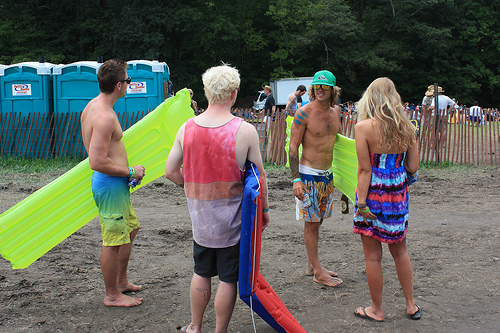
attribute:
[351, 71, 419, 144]
hair — long, blonde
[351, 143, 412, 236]
dress — multi-colored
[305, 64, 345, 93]
hat — green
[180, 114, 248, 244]
tank top — pink, grey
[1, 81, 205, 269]
float — yellow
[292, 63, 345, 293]
man — green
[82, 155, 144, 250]
shorts — multicolored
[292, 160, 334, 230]
shorts — multicolored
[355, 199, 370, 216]
bracelet — green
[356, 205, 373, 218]
wrist — girl's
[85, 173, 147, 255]
shorts — blue, yellow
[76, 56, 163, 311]
guy — brown haired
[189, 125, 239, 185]
section — red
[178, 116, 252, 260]
top — tank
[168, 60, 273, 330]
guy — blond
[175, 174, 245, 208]
section — brown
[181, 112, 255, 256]
top — tank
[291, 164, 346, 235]
shorts — multicolored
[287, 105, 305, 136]
stripes — three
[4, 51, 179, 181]
potties — three, porta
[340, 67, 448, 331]
girl — blonde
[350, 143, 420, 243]
dress — summer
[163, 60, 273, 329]
man — blond, barefoot, young, blonde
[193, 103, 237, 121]
neck — sunburned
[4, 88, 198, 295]
sunbed — bright yellow, inflatable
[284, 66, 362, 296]
man — shirtless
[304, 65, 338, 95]
cap — green, baseball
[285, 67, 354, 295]
man — shirtless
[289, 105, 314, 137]
paint — blue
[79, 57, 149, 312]
man — barefoot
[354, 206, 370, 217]
bracelet — green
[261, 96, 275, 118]
shirt — black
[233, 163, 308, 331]
raft — blue, red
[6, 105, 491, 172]
fence — wooden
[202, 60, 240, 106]
hair — blonde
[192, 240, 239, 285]
shorts — black